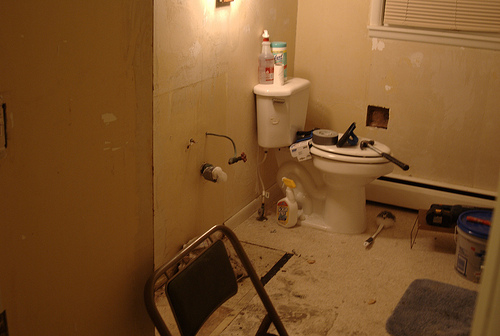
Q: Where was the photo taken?
A: It was taken at the bathroom.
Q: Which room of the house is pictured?
A: It is a bathroom.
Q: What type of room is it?
A: It is a bathroom.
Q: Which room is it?
A: It is a bathroom.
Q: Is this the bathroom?
A: Yes, it is the bathroom.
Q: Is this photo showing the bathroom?
A: Yes, it is showing the bathroom.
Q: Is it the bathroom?
A: Yes, it is the bathroom.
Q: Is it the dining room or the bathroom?
A: It is the bathroom.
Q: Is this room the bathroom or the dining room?
A: It is the bathroom.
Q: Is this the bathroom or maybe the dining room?
A: It is the bathroom.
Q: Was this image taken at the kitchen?
A: No, the picture was taken in the bathroom.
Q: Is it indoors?
A: Yes, it is indoors.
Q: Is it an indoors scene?
A: Yes, it is indoors.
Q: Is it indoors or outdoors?
A: It is indoors.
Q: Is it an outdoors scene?
A: No, it is indoors.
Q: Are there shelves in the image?
A: No, there are no shelves.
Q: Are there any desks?
A: No, there are no desks.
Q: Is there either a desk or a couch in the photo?
A: No, there are no desks or couches.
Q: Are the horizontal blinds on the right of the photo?
A: Yes, the blinds are on the right of the image.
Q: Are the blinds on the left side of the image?
A: No, the blinds are on the right of the image.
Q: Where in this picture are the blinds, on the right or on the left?
A: The blinds are on the right of the image.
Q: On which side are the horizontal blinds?
A: The blinds are on the right of the image.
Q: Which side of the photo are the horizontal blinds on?
A: The blinds are on the right of the image.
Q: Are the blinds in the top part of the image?
A: Yes, the blinds are in the top of the image.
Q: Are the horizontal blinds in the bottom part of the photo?
A: No, the blinds are in the top of the image.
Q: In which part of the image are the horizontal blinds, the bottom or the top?
A: The blinds are in the top of the image.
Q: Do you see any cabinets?
A: No, there are no cabinets.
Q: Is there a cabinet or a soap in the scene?
A: No, there are no cabinets or soaps.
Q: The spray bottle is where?
A: The spray bottle is on the floor.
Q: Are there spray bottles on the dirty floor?
A: Yes, there is a spray bottle on the floor.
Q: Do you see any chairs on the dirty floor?
A: No, there is a spray bottle on the floor.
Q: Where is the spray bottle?
A: The spray bottle is in the bathroom.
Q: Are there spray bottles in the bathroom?
A: Yes, there is a spray bottle in the bathroom.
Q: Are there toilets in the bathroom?
A: No, there is a spray bottle in the bathroom.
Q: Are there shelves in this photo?
A: No, there are no shelves.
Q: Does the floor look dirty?
A: Yes, the floor is dirty.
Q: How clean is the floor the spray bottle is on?
A: The floor is dirty.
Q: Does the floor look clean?
A: No, the floor is dirty.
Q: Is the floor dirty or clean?
A: The floor is dirty.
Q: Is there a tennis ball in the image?
A: No, there are no tennis balls.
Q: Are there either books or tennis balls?
A: No, there are no tennis balls or books.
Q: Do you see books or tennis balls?
A: No, there are no tennis balls or books.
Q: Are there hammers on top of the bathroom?
A: Yes, there is a hammer on top of the bathroom.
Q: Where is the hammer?
A: The hammer is in the bathroom.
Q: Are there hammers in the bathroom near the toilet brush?
A: Yes, there is a hammer in the bathroom.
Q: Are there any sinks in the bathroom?
A: No, there is a hammer in the bathroom.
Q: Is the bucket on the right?
A: Yes, the bucket is on the right of the image.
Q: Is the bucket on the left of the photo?
A: No, the bucket is on the right of the image.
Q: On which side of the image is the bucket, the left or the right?
A: The bucket is on the right of the image.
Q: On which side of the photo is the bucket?
A: The bucket is on the right of the image.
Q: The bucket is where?
A: The bucket is in the bathroom.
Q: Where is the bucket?
A: The bucket is in the bathroom.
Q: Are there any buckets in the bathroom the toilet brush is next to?
A: Yes, there is a bucket in the bathroom.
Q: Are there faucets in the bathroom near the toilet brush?
A: No, there is a bucket in the bathroom.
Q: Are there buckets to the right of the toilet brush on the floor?
A: Yes, there is a bucket to the right of the toilet brush.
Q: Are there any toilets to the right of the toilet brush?
A: No, there is a bucket to the right of the toilet brush.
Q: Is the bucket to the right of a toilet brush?
A: Yes, the bucket is to the right of a toilet brush.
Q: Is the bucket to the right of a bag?
A: No, the bucket is to the right of a toilet brush.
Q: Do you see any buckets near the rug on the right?
A: Yes, there is a bucket near the rug.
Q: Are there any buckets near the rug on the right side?
A: Yes, there is a bucket near the rug.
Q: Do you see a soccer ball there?
A: No, there are no soccer balls.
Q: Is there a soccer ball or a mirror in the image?
A: No, there are no soccer balls or mirrors.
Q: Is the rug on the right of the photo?
A: Yes, the rug is on the right of the image.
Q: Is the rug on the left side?
A: No, the rug is on the right of the image.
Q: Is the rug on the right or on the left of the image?
A: The rug is on the right of the image.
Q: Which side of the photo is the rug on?
A: The rug is on the right of the image.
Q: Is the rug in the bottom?
A: Yes, the rug is in the bottom of the image.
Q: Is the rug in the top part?
A: No, the rug is in the bottom of the image.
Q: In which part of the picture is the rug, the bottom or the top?
A: The rug is in the bottom of the image.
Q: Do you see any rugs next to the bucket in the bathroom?
A: Yes, there is a rug next to the bucket.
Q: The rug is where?
A: The rug is in the bathroom.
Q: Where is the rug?
A: The rug is in the bathroom.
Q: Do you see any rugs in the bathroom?
A: Yes, there is a rug in the bathroom.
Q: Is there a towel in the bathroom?
A: No, there is a rug in the bathroom.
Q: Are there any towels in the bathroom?
A: No, there is a rug in the bathroom.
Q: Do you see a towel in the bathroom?
A: No, there is a rug in the bathroom.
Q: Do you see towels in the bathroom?
A: No, there is a rug in the bathroom.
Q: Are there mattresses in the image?
A: No, there are no mattresses.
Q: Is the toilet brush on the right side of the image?
A: Yes, the toilet brush is on the right of the image.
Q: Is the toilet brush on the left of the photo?
A: No, the toilet brush is on the right of the image.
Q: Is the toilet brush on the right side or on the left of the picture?
A: The toilet brush is on the right of the image.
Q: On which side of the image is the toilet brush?
A: The toilet brush is on the right of the image.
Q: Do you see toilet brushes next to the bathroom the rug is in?
A: Yes, there is a toilet brush next to the bathroom.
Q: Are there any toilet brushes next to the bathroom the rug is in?
A: Yes, there is a toilet brush next to the bathroom.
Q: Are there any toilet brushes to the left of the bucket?
A: Yes, there is a toilet brush to the left of the bucket.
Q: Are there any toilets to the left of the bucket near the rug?
A: No, there is a toilet brush to the left of the bucket.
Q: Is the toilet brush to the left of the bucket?
A: Yes, the toilet brush is to the left of the bucket.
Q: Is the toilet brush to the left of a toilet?
A: No, the toilet brush is to the left of the bucket.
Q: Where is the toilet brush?
A: The toilet brush is on the floor.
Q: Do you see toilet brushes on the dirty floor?
A: Yes, there is a toilet brush on the floor.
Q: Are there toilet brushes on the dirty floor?
A: Yes, there is a toilet brush on the floor.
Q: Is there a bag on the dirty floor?
A: No, there is a toilet brush on the floor.